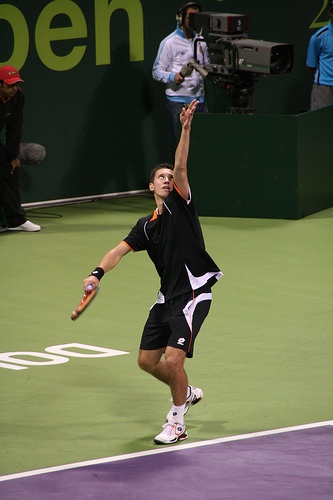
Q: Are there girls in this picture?
A: No, there are no girls.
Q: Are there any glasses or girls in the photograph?
A: No, there are no girls or glasses.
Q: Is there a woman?
A: No, there are no women.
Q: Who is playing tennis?
A: The man is playing tennis.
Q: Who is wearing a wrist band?
A: The man is wearing a wrist band.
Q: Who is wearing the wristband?
A: The man is wearing a wrist band.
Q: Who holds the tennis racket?
A: The man holds the tennis racket.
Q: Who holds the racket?
A: The man holds the tennis racket.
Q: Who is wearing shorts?
A: The man is wearing shorts.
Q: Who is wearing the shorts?
A: The man is wearing shorts.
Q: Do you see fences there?
A: No, there are no fences.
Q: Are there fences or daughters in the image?
A: No, there are no fences or daughters.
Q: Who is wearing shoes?
A: The man is wearing shoes.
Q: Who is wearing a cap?
A: The man is wearing a cap.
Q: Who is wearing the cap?
A: The man is wearing a cap.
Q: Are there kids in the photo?
A: No, there are no kids.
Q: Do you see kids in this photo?
A: No, there are no kids.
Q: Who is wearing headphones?
A: The man is wearing headphones.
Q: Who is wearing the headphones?
A: The man is wearing headphones.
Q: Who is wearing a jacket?
A: The man is wearing a jacket.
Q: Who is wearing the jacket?
A: The man is wearing a jacket.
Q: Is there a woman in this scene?
A: No, there are no women.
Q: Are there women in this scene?
A: No, there are no women.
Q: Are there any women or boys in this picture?
A: No, there are no women or boys.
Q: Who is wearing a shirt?
A: The man is wearing a shirt.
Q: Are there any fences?
A: No, there are no fences.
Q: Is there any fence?
A: No, there are no fences.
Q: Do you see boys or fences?
A: No, there are no fences or boys.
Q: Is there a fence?
A: No, there are no fences.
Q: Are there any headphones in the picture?
A: Yes, there are headphones.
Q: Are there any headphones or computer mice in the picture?
A: Yes, there are headphones.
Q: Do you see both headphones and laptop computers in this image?
A: No, there are headphones but no laptops.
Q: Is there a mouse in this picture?
A: No, there are no computer mice.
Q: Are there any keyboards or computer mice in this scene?
A: No, there are no computer mice or keyboards.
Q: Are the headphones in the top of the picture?
A: Yes, the headphones are in the top of the image.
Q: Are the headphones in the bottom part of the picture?
A: No, the headphones are in the top of the image.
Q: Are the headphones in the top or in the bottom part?
A: The headphones are in the top of the image.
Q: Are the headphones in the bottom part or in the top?
A: The headphones are in the top of the image.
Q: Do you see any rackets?
A: Yes, there is a racket.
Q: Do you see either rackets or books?
A: Yes, there is a racket.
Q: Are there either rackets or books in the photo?
A: Yes, there is a racket.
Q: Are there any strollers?
A: No, there are no strollers.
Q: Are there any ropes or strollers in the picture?
A: No, there are no strollers or ropes.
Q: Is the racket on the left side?
A: Yes, the racket is on the left of the image.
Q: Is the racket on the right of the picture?
A: No, the racket is on the left of the image.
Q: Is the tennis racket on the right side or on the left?
A: The tennis racket is on the left of the image.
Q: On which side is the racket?
A: The racket is on the left of the image.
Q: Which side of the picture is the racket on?
A: The racket is on the left of the image.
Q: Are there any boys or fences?
A: No, there are no fences or boys.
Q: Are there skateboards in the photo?
A: No, there are no skateboards.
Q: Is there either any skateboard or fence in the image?
A: No, there are no skateboards or fences.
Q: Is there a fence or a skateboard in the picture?
A: No, there are no skateboards or fences.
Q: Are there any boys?
A: No, there are no boys.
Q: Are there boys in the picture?
A: No, there are no boys.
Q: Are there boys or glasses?
A: No, there are no boys or glasses.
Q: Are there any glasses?
A: No, there are no glasses.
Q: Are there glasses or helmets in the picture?
A: No, there are no glasses or helmets.